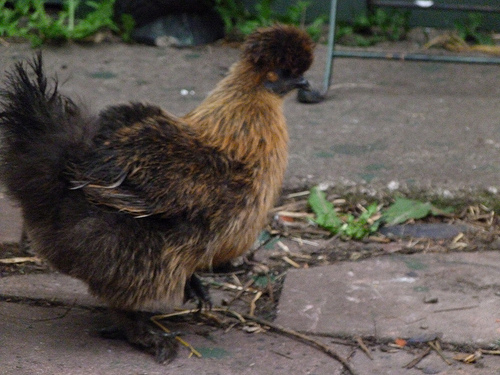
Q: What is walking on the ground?
A: A chicken.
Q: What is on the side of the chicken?
A: A wing.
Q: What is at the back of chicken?
A: It's tail.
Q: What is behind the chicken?
A: Metal pole.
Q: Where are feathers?
A: On chicken.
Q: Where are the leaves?
A: On road.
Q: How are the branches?
A: Broken.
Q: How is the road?
A: Broken.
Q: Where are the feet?
A: On chicken.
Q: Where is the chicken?
A: On ground.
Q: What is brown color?
A: Bird.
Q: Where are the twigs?
A: In cracks.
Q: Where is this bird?
A: On the pavement.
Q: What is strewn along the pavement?
A: Leaves and dirt.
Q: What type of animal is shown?
A: A bird.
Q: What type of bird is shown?
A: A hen.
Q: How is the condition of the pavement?
A: Cracked.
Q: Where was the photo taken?
A: Outside on cement.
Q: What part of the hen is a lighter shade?
A: The neck and breast.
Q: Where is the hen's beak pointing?
A: Toward the right.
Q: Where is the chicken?
A: On the road.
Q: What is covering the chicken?
A: Feathers.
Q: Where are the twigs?
A: On the ground.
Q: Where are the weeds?
A: In the back behind the chicken.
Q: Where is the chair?
A: Behind the chicken.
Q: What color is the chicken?
A: Brown.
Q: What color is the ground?
A: Grey.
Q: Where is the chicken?
A: The farm.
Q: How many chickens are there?
A: One.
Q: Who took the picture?
A: My cousin.